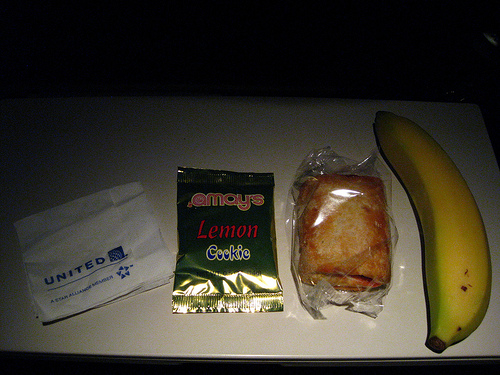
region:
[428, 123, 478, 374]
a yellow and brown banana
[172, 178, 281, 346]
a package of lemon cookies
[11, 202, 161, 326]
white and blue napkins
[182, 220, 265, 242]
red letters that say lemon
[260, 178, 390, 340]
a desert in a package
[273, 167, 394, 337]
desert in clear plastic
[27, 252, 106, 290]
blue letters that say united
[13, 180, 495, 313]
banana cookie napkins and desert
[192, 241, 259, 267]
blue letters that say cookie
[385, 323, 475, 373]
brown bottom of banana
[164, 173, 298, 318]
a lemon cookie in a wrapper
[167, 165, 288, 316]
a golden wrapper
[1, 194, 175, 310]
a white napkin on a table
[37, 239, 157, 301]
blue logo of a plane company on a napkin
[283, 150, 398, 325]
a cherry pie in a plastic wrapper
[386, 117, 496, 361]
a yellow banana on a table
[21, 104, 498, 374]
a small table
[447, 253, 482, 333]
brown spots on a banana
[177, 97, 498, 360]
various desserts on table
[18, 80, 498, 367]
a banana, a cookie, a cherry pie and a napkin on a table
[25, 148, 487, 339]
Airplane food on tray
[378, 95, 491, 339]
Yellow banana is unpeeled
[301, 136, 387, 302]
Small pastry in wrapper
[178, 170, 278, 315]
Lemon cookie in shiny container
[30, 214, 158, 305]
Sugar in packet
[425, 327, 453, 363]
Tip is brown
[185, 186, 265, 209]
Brand is Emoys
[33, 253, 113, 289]
United written on package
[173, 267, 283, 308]
Golden package is gleaming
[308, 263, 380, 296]
Edge of pastry is red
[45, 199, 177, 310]
A white napkin on the table.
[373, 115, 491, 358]
A yellow banana on the white table.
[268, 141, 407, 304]
A sandwich wrapped in wrapper.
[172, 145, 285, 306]
A package of lemon cookies.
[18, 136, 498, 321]
Food on a white table.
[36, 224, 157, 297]
The napkin has United written on it.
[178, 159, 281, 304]
The packaging is green.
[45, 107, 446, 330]
The table is white.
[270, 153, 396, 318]
The wrapper is clear.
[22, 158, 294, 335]
The napkin is next to the cookie.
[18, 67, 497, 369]
food on a table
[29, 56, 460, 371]
food in a row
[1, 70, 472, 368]
food in a line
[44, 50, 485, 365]
unopen food on the table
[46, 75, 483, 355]
food that has not been open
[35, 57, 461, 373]
food that has not been consumed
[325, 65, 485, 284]
a yellow unopen banana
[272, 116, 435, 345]
a food in a package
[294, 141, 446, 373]
food in a clear package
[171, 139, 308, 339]
a pack of lemon cooki